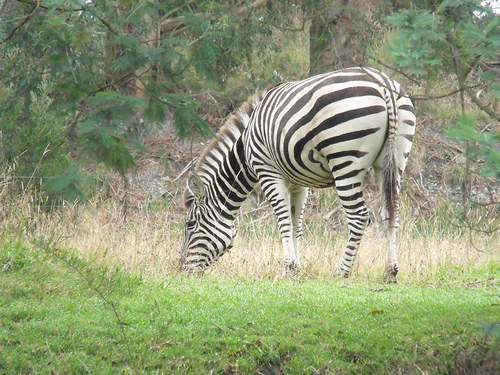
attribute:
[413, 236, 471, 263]
grass — over grown, brown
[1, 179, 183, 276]
grass — dead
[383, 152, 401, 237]
tail — white, black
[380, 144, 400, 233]
fur — long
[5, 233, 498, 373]
grass — brown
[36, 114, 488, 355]
grass — lively, green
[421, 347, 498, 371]
patch — grass